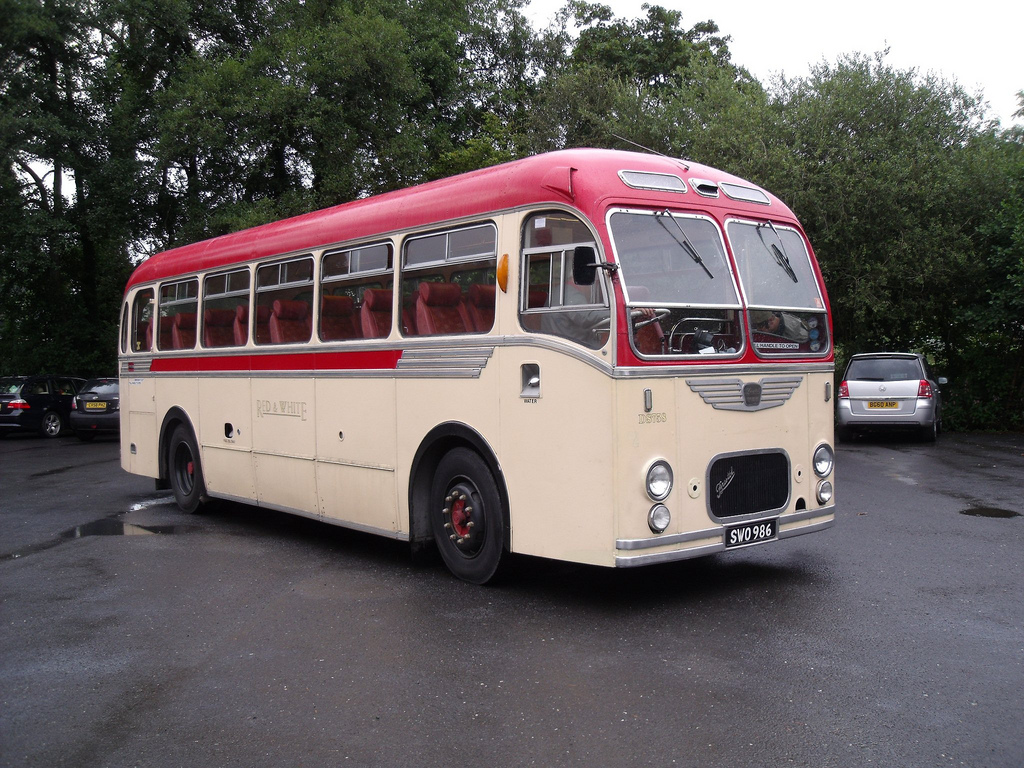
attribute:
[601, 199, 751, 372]
windshield — larger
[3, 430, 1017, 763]
road — black, paved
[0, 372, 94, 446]
van — long, black, parked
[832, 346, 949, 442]
car — silver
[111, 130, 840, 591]
bus — red, off white, large, white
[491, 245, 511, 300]
light — orange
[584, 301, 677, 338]
steering wheel — large, round, metal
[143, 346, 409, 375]
stripe — red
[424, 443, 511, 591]
tire — large, round, black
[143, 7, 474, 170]
leaves — many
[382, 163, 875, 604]
bus — numbered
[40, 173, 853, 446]
bus — orange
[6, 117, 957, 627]
bus — red, tan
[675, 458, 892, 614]
plate — black, white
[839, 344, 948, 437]
van — silver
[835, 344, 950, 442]
van — silver, parked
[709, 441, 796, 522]
grill — black, bus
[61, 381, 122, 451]
car — parked, dark grey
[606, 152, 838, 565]
front — bus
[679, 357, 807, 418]
wings — silver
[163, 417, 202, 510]
tire — back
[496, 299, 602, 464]
wings — silver 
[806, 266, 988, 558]
hatchback — silver 